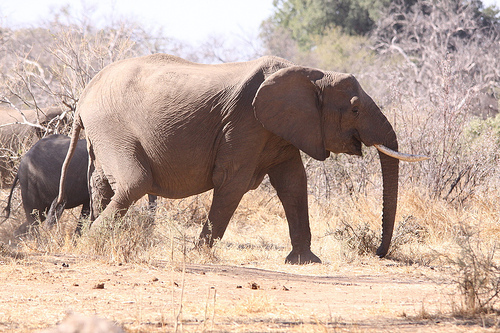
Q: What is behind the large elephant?
A: A small elephant.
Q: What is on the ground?
A: Dirt.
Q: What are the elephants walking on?
A: Dirt.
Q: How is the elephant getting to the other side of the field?
A: Walking.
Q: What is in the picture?
A: Elephants.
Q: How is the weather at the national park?
A: Sunny.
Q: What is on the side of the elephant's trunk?
A: Tusk.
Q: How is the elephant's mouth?
A: Open.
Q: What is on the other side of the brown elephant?
A: A black elephant.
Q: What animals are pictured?
A: Two elephants.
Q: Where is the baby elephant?
A: Behind the adult elephant.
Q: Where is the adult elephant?
A: In front of the baby elephant.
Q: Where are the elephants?
A: In the wild.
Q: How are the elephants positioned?
A: Standing.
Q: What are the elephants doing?
A: Walking.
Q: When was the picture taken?
A: During day hours.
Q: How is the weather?
A: Sunny.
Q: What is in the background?
A: Trees and bushes.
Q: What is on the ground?
A: Dirt.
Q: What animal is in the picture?
A: Elephant.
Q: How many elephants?
A: Two.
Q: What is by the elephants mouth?
A: Tusks.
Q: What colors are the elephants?
A: Grey and brown.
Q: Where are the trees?
A: In background.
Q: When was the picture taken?
A: Daytime.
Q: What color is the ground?
A: Brown.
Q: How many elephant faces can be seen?
A: One.